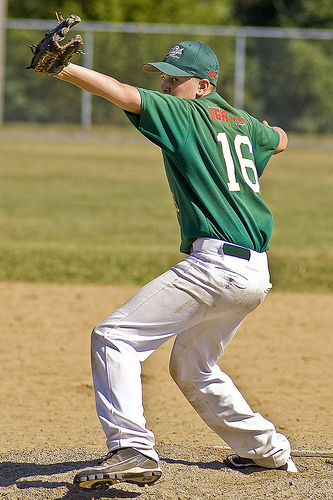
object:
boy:
[23, 8, 300, 496]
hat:
[140, 37, 221, 91]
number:
[214, 130, 241, 195]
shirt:
[121, 86, 281, 258]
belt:
[216, 243, 252, 263]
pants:
[88, 233, 290, 471]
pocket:
[213, 263, 249, 292]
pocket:
[262, 280, 275, 295]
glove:
[24, 10, 86, 79]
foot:
[223, 447, 299, 474]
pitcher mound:
[1, 431, 333, 499]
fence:
[0, 16, 333, 152]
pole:
[233, 32, 246, 112]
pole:
[79, 28, 97, 134]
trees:
[0, 1, 333, 134]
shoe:
[71, 441, 165, 497]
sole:
[71, 465, 163, 495]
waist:
[185, 218, 273, 265]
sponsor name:
[206, 105, 247, 125]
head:
[159, 37, 221, 100]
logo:
[163, 42, 185, 61]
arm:
[54, 63, 192, 152]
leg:
[90, 259, 215, 466]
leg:
[167, 315, 295, 471]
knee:
[90, 315, 112, 361]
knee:
[168, 348, 187, 394]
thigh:
[94, 253, 213, 363]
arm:
[245, 108, 290, 156]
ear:
[194, 77, 211, 97]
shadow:
[1, 451, 268, 498]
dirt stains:
[88, 252, 293, 476]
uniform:
[89, 86, 294, 473]